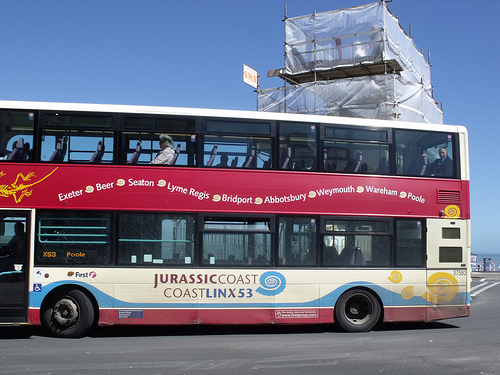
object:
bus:
[1, 100, 472, 337]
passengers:
[1, 108, 462, 179]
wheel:
[40, 287, 96, 339]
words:
[153, 274, 258, 289]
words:
[57, 179, 427, 204]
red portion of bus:
[0, 163, 469, 218]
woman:
[152, 135, 176, 165]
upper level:
[2, 100, 470, 200]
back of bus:
[370, 119, 471, 324]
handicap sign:
[34, 284, 43, 292]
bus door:
[0, 210, 33, 327]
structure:
[257, 0, 443, 125]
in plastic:
[284, 1, 385, 77]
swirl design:
[259, 270, 286, 298]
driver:
[1, 221, 25, 274]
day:
[1, 0, 500, 128]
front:
[1, 101, 114, 352]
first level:
[1, 187, 472, 336]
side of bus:
[1, 100, 470, 326]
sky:
[1, 0, 500, 129]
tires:
[40, 285, 96, 338]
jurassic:
[155, 274, 219, 287]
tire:
[336, 287, 382, 331]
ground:
[1, 333, 498, 374]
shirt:
[151, 148, 176, 166]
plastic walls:
[253, 0, 443, 125]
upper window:
[119, 112, 202, 171]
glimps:
[470, 252, 499, 273]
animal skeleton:
[0, 163, 59, 203]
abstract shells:
[387, 271, 459, 304]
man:
[421, 148, 454, 178]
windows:
[36, 209, 427, 270]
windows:
[1, 108, 461, 180]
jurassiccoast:
[153, 273, 259, 288]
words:
[163, 287, 239, 299]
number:
[238, 289, 245, 299]